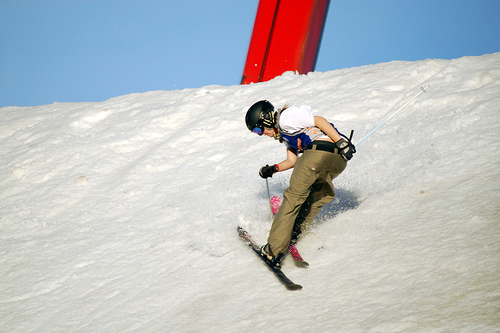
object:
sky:
[1, 0, 498, 108]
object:
[242, 0, 331, 82]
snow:
[3, 53, 496, 332]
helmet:
[245, 100, 273, 130]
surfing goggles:
[252, 120, 264, 135]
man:
[245, 100, 353, 267]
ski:
[237, 225, 301, 290]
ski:
[271, 196, 307, 265]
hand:
[259, 164, 278, 178]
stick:
[265, 177, 270, 200]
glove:
[335, 138, 356, 161]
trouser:
[266, 143, 347, 268]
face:
[263, 129, 273, 138]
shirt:
[280, 105, 339, 157]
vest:
[278, 106, 347, 150]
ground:
[0, 143, 500, 332]